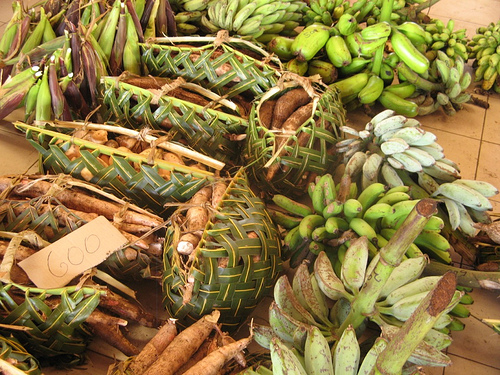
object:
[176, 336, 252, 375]
brown food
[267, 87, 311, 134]
brown food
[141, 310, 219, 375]
brown food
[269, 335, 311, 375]
banana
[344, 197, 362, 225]
banana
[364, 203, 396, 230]
banana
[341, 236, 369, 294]
banana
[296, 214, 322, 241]
banana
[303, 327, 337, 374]
bananas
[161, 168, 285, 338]
baskets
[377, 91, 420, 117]
fruits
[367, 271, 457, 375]
bunches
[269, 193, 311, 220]
fruit vegetables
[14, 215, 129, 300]
sign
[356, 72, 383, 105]
bananas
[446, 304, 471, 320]
fruits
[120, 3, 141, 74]
vegetables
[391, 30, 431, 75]
food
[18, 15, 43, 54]
fruit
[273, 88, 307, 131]
root vegetables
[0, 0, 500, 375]
ground